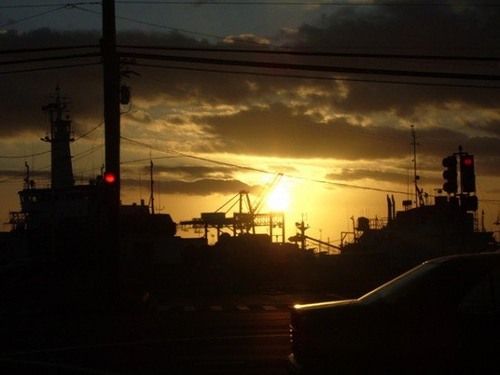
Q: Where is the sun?
A: Under the clouds.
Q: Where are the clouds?
A: In the sky.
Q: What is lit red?
A: The traffic lights.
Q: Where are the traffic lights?
A: On poles.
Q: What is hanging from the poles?
A: Electrical wires.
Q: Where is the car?
A: On the street.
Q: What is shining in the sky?
A: The sun.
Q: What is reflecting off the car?
A: Sunlight.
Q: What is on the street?
A: Car.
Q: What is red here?
A: A street light.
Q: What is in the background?
A: Sun.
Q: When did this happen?
A: Sunset.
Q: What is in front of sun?
A: Crane.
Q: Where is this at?
A: A street.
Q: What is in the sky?
A: Clouds.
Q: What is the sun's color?
A: Yellow.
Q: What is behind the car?
A: Buildings.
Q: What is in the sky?
A: Clouds.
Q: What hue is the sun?
A: Yellow.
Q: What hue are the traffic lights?
A: Red.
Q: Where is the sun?
A: Low on the horizon.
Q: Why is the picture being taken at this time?
A: To catch the sun low on the horizon.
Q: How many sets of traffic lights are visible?
A: Two.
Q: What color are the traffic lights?
A: Red.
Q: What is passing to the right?
A: A car.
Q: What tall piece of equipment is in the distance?
A: A crane.